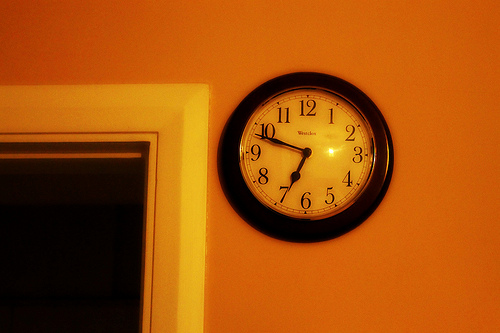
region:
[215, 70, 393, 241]
a clock is on the wall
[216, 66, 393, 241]
the clock is framed in brown wood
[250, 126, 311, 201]
the hands of the clock are black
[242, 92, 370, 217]
the numbers on the clock are black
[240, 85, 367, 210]
the face of the clock is white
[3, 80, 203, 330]
a wood trim around the door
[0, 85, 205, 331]
the wood trim is white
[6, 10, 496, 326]
the walls are painted an orange color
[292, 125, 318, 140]
the name of the maker of the clock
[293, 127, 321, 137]
the name of the manufacturer of the wall clock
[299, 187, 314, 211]
a number 6 in a watch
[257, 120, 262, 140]
a number 1 in a watch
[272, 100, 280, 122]
a number 1 in a watch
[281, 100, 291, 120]
a number 1 in a watch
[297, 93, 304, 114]
a number 1 in a watch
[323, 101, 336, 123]
a number 1 in a watch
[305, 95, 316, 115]
a number 2 in a watch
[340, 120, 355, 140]
a number 2 in a watch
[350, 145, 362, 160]
a number 3 in a watch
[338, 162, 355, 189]
a number 4 in a watch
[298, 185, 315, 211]
a number 6 on a clock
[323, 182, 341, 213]
a number 5 on a clock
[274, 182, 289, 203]
a number 7 on a clock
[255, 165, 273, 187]
a number 8 on a clock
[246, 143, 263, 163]
a number 9 on a clock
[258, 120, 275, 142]
a number 10 on a clock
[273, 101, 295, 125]
a number 11 on a clock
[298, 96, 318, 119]
a number 12 on a clock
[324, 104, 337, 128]
a number 1 on a clock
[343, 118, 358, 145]
a number 2 on a clock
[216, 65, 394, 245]
black and white clock on the wall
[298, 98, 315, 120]
the number twelve printed in black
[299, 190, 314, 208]
the number six printed in black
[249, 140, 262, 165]
the number nine printed in black text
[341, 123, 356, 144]
the number two printed on the clock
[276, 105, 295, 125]
the number eleven printed on the clock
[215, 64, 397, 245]
clock with a black round rim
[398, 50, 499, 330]
wall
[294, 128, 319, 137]
black text of the clock's brand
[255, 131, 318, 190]
two black clock hands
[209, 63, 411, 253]
an analog clock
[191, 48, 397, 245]
the clock is black and white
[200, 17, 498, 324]
the wall is peach colored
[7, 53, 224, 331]
the doorway trim is white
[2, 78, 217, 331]
the doorway is dark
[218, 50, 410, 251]
the clock's face is white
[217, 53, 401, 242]
the numbers are black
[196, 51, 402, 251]
the clock is round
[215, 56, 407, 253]
the clock has hands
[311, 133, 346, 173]
the clock has a reflection of a light on it